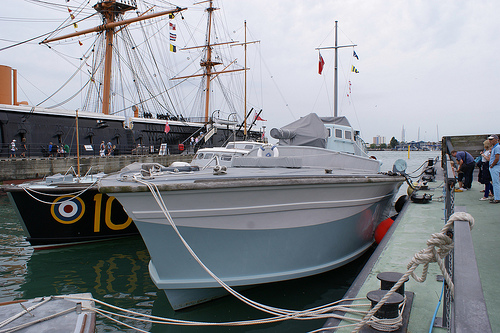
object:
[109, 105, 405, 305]
ship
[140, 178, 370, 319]
thread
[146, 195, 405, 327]
thread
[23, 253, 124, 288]
water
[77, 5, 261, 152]
pole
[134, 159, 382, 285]
boat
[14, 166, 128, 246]
boat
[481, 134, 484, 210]
man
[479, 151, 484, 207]
woman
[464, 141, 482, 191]
man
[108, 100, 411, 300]
boat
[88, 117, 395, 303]
boat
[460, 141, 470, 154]
man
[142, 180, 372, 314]
rope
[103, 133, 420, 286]
boat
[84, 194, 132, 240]
boat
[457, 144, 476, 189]
man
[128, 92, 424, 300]
ship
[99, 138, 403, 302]
boat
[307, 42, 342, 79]
flag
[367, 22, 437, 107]
sky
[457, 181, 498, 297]
dock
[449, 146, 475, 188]
man